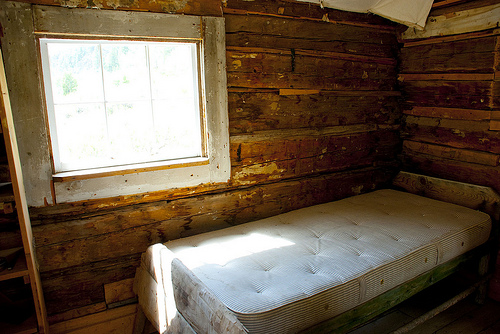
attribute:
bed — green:
[134, 169, 499, 333]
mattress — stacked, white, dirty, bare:
[161, 188, 493, 334]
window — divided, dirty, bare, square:
[37, 35, 211, 173]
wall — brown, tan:
[2, 1, 404, 329]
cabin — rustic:
[2, 1, 499, 332]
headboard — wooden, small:
[392, 168, 499, 213]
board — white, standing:
[106, 274, 141, 307]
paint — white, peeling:
[4, 4, 234, 209]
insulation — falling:
[294, 2, 437, 32]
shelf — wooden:
[1, 119, 32, 333]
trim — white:
[0, 2, 235, 208]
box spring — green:
[300, 241, 494, 333]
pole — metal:
[383, 271, 497, 332]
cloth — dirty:
[132, 245, 179, 334]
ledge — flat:
[51, 156, 212, 186]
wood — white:
[2, 2, 232, 208]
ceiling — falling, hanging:
[297, 2, 435, 30]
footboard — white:
[165, 250, 250, 334]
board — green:
[305, 240, 493, 333]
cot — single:
[164, 186, 495, 333]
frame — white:
[2, 1, 231, 209]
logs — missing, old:
[1, 1, 499, 320]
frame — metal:
[369, 256, 500, 332]